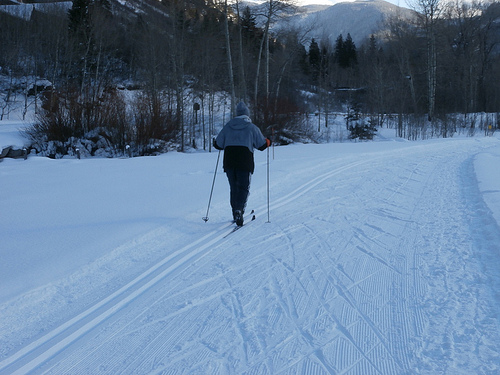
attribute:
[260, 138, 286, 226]
pole — ski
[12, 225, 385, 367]
ground — white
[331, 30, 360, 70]
leaves — green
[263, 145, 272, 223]
long/thin ski-pole — long, thin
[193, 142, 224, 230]
long/thin ski-pole — thin, long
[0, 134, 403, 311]
snow — smooth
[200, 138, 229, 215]
pole — ski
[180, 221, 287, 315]
snow — white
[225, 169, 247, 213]
pant. — black